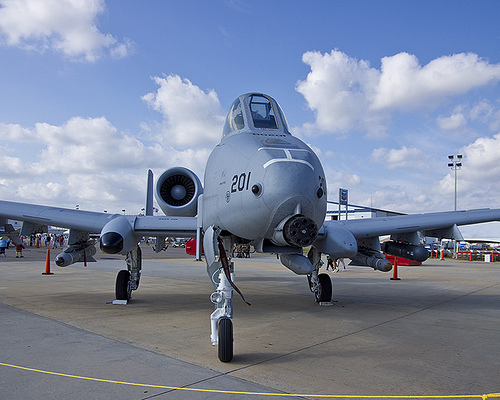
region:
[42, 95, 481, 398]
GRAY A10 WARTHOG ON TARMAC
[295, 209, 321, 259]
LARGE GUN ON FRONT OF PLANE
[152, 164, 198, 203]
ENGINE NEAR THE REAR OF PLANE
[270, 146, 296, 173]
WHITE LINES ON NOSE OF PLANE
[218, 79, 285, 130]
GLASS COCKPIT OF PLANE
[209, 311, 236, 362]
BLACK TIRE ON LANDING GEAR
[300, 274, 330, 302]
BLACK TIRE ON LANDING GEAR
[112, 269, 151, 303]
BLACK TIRE ON LANDING GEAR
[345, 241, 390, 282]
MISSLE LOCATED UNDER WING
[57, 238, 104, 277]
MISSLE LOCATED UNDER WING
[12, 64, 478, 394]
gray a10 warthog on tarmac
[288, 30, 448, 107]
white clouds in blue sky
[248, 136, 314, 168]
white lines on aircraft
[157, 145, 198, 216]
large engine near tail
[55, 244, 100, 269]
missle located under wing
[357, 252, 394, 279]
missle located under wing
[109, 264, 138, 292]
black tire on tarmac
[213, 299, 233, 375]
black tire on tarmac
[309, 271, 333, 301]
black tire on tarmac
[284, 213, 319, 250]
large gun on front of plane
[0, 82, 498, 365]
A jet is in the foreground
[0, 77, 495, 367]
Gray jet is on the ground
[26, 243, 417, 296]
Orange colored cones on the ground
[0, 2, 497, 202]
White clouds in the sky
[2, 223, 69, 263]
People in the background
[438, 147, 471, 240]
A light pole in the background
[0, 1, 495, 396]
Photo was taken in the daytime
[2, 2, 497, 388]
Photo was taken outdoors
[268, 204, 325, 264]
A minigun is in the front of the jet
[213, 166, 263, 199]
The number "201" is on the side of the jet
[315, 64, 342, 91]
part of a cloud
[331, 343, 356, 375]
part of a floor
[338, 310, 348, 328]
part of a floor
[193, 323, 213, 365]
part of a floor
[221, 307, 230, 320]
part if a handk,e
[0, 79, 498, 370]
a plane on an airport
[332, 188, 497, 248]
right wing of plane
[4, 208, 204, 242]
left wing of plane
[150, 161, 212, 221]
engine on left side of plane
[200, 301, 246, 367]
front wheel of plane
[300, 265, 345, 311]
right wheel of plane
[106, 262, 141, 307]
left wheel of plane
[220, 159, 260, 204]
airplane number 201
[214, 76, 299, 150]
windows of cockpit of plane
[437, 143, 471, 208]
lights on a pole